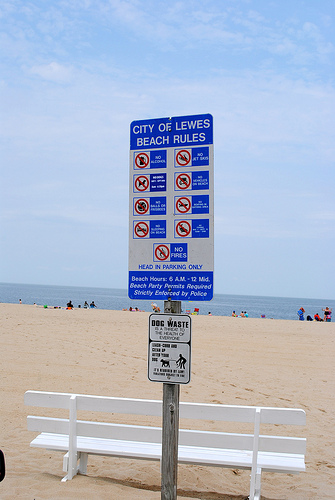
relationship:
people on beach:
[3, 292, 332, 330] [2, 292, 331, 493]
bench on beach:
[15, 388, 316, 493] [3, 295, 321, 320]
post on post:
[127, 113, 215, 302] [160, 300, 181, 496]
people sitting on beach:
[231, 291, 333, 330] [37, 279, 202, 394]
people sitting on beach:
[87, 298, 98, 308] [3, 293, 332, 336]